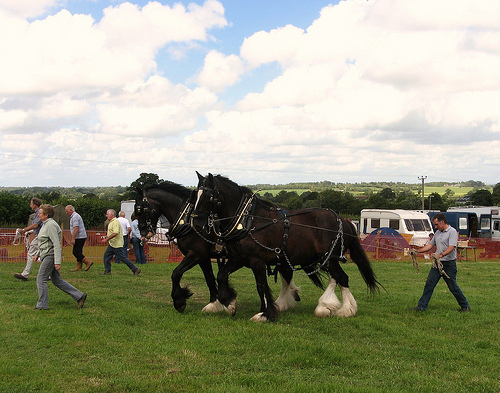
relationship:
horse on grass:
[130, 177, 302, 312] [6, 242, 498, 389]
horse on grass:
[187, 170, 388, 322] [6, 242, 498, 389]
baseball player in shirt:
[32, 203, 87, 310] [34, 217, 64, 264]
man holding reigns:
[409, 211, 471, 315] [249, 212, 446, 275]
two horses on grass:
[103, 170, 456, 310] [4, 227, 484, 381]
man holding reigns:
[409, 211, 471, 315] [249, 212, 452, 275]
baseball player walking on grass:
[32, 203, 87, 310] [31, 314, 206, 373]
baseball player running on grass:
[32, 203, 87, 310] [0, 252, 497, 393]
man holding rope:
[409, 211, 471, 315] [289, 220, 441, 270]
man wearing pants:
[409, 211, 471, 315] [409, 259, 470, 314]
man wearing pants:
[104, 208, 140, 276] [36, 255, 83, 310]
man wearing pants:
[59, 202, 95, 274] [101, 242, 136, 276]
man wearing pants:
[118, 208, 133, 261] [129, 235, 149, 264]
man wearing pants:
[12, 195, 37, 280] [23, 251, 37, 278]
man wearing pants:
[59, 202, 95, 274] [71, 239, 87, 260]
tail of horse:
[341, 217, 385, 297] [102, 167, 413, 349]